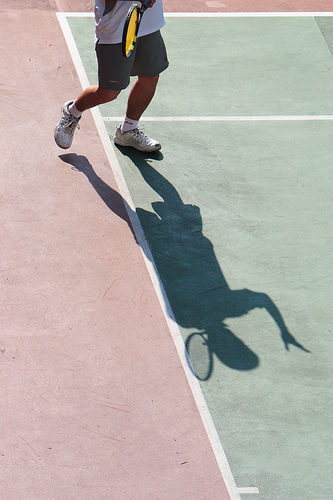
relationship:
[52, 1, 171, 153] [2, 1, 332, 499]
person on court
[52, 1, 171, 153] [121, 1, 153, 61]
person holding racket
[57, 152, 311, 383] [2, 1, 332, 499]
shadow on court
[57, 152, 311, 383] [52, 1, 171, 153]
shadow of person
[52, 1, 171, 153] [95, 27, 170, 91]
person has shorts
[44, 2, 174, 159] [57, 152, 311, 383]
tennis player has shadow